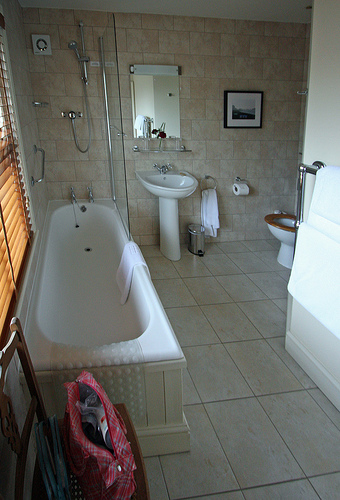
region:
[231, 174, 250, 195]
roll of toilet paper on metal holder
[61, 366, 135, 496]
a pink with white design bag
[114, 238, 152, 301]
a white towel folded over tub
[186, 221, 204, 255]
a shiny metal and black trash can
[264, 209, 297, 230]
a wooden toilet seat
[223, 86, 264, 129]
a black framed portrait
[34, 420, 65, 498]
a small blue bag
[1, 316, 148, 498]
a wooden framed chair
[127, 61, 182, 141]
a frameless bathroom mirror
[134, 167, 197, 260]
a white porcelain sink under mirror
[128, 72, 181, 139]
mirror above the sink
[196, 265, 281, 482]
tiled bathroom floor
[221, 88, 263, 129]
framed artwork on the wall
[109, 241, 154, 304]
white towel hanging over the edge of the bathtub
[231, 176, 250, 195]
toilet paper holder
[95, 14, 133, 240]
glass partition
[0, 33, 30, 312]
window above the bathtub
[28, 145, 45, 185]
safety bar attached to the wall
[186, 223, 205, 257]
silver trashcan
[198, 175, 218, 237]
white towel hanging by the sink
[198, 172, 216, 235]
A white towel is hanging on the towel rack.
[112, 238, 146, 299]
A white bath mat is draped over the bathtub.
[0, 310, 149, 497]
A wooden chair.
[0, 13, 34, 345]
The blinds are hanging.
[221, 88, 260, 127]
A picture is on the wall.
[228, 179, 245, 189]
Toilet paper is white.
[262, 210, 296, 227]
The toilet seat is brown.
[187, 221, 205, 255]
The trash can is on the floor.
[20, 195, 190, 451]
The bathtub is rectangular.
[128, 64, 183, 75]
The light is off.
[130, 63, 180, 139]
a mirror in a bathroom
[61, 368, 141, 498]
a pink plaid bag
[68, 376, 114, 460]
an unzipped bag zipper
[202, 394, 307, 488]
a beige floor tile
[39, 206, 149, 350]
an oblong tub basin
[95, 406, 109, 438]
a white tube inside a bag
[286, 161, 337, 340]
two white towels hanging on a rack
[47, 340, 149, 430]
a knobby bathtub mat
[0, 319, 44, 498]
the wooden back of a chair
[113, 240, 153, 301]
a white towel hanging over the tub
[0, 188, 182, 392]
this is a bath tub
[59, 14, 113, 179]
this is the shower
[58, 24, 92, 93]
this is the shower head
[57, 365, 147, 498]
a red toiletry bag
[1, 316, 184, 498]
a wooden chair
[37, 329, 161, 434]
a plastic grip mat for a tub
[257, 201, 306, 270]
this is the toilet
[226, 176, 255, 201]
a roll of toilet paper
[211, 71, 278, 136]
a framed photograph on the wall